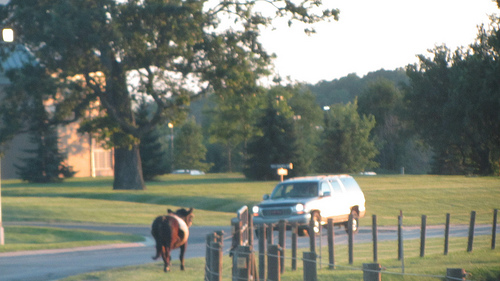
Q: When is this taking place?
A: Daytime.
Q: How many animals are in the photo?
A: One.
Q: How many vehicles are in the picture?
A: One.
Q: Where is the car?
A: Street.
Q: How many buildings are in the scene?
A: One.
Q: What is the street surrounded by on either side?
A: Grass.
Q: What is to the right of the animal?
A: Fence.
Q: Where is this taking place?
A: The sidewalk.